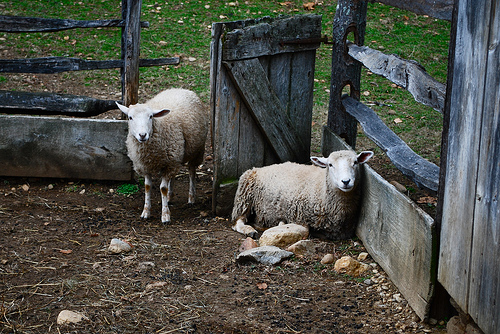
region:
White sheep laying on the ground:
[228, 147, 378, 244]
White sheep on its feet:
[111, 83, 210, 224]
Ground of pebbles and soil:
[0, 177, 423, 332]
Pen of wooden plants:
[0, 0, 499, 332]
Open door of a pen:
[142, 0, 327, 220]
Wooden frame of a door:
[208, 12, 321, 219]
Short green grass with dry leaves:
[1, 2, 454, 176]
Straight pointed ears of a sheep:
[305, 148, 377, 169]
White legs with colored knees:
[137, 175, 174, 227]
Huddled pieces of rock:
[235, 221, 373, 273]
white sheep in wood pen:
[118, 91, 213, 231]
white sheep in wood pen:
[234, 141, 384, 221]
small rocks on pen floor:
[241, 224, 313, 262]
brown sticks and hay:
[53, 226, 204, 328]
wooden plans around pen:
[335, 144, 470, 296]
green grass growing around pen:
[148, 22, 205, 48]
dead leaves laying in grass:
[150, 15, 206, 32]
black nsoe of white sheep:
[343, 176, 355, 191]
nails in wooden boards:
[459, 261, 478, 282]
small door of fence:
[205, 24, 340, 166]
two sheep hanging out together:
[116, 84, 371, 239]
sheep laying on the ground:
[229, 141, 376, 231]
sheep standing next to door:
[115, 90, 213, 218]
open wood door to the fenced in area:
[208, 13, 311, 226]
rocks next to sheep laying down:
[244, 217, 366, 295]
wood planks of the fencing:
[4, 6, 464, 208]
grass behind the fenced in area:
[3, 2, 463, 174]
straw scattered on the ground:
[9, 190, 367, 331]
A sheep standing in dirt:
[113, 84, 209, 223]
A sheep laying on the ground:
[226, 147, 372, 236]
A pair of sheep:
[114, 84, 374, 243]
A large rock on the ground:
[258, 220, 310, 248]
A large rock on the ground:
[237, 244, 292, 268]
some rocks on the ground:
[56, 224, 406, 326]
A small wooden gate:
[206, 10, 319, 216]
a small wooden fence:
[0, 1, 182, 190]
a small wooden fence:
[317, 1, 498, 332]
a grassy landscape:
[2, 0, 451, 167]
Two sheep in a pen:
[106, 83, 380, 249]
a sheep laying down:
[228, 144, 374, 241]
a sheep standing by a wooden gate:
[114, 84, 216, 229]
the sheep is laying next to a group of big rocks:
[230, 218, 339, 271]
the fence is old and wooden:
[0, 0, 460, 216]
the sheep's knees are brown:
[139, 179, 171, 199]